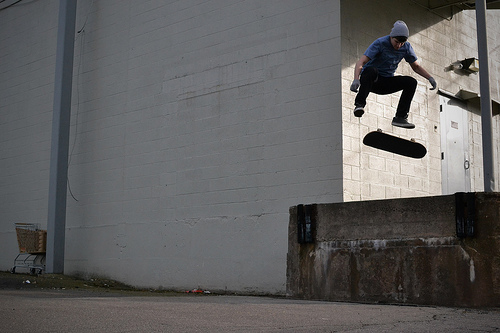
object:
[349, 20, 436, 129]
boy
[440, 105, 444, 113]
hinge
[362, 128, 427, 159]
board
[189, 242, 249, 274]
stunt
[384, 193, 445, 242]
ground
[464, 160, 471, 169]
handle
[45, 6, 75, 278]
pole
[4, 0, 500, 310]
building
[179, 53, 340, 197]
brick wall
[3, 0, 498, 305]
wall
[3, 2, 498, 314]
white brick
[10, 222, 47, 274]
shopping cart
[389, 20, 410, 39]
beanie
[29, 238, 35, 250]
plastic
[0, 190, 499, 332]
blocks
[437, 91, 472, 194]
door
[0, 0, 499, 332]
air